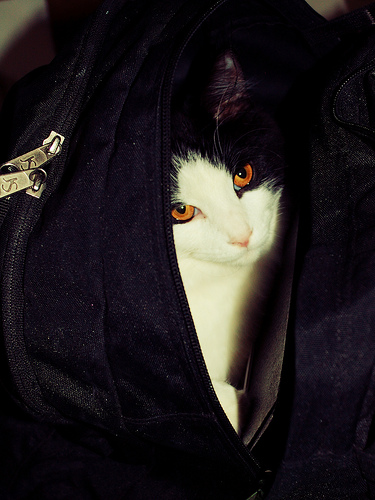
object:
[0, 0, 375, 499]
bag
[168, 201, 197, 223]
eye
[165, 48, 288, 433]
cat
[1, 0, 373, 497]
luggage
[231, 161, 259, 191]
eye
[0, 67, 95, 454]
zipper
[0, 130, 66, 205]
zipper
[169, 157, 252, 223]
cat's eyes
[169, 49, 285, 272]
head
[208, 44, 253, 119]
cat ear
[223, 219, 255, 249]
nose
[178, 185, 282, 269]
whiskers